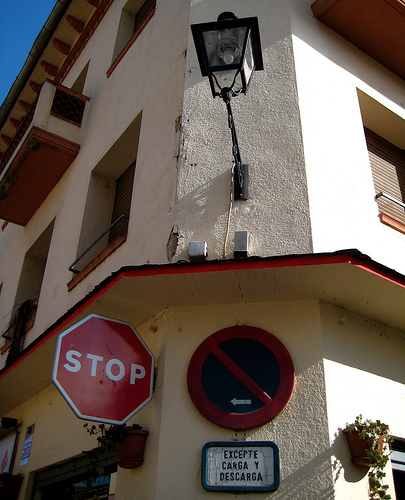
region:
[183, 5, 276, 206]
The outdoor light is off.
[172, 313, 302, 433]
The sign is round.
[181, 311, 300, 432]
The sign is red, black and white.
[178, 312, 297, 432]
The sign has an arrow on it.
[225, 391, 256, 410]
The arrow is white.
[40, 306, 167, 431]
The sign is red and white.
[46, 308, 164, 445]
The sign is octagonal.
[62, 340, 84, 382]
The letter is white.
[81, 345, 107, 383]
The letter is white.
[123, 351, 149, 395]
The letter is white.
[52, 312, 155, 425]
sign in shape of an octogon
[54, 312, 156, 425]
red and white sign on side of building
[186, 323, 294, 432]
red and black sign on side of building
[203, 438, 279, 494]
blue and white sign on side of building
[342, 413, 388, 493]
brown flower pot on side of building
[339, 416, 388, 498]
plant growing from brown pot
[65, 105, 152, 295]
window on side of building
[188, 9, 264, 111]
black light on corner of building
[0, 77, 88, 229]
tan and brown balcony on side of building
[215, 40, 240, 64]
light bulb in socket on corner of building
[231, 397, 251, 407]
a white arrow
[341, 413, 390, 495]
a plant hanging on the wall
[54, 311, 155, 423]
red and white stop sign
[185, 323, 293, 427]
a red no sign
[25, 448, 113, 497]
a doorway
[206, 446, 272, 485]
white sign with dark lettering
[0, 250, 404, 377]
red trim on the over hang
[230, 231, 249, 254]
silver power box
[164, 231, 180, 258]
broken piece of the wall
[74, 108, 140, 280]
second story window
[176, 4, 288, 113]
this is a light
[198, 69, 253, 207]
attachment to the light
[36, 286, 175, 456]
this is a sign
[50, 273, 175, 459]
the sign is an octagon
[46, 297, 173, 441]
the sign is red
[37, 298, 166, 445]
white writing on sign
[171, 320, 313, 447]
this is a red and black sign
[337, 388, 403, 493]
potted plant attached to building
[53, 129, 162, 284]
this is a window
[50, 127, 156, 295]
the window has shutters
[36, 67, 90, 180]
a small balcony on a building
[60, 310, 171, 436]
a traffic sign mounted to a building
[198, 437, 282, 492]
a framed sign on a building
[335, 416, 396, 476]
a clay flower pot attached to a building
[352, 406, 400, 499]
a green vine growing in a pot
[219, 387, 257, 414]
a white arrow on a sign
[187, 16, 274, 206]
a black light mounted to a building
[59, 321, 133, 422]
a red and white traffic sign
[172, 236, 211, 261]
a electrical box on a building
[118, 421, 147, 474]
a brown clay flower pot